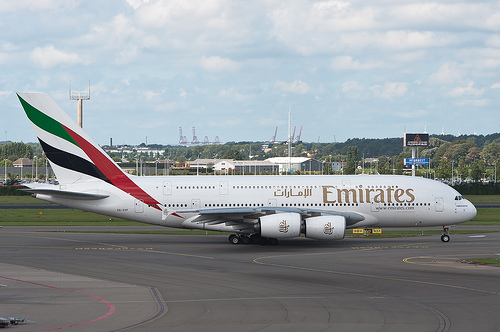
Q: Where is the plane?
A: On the runway.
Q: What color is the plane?
A: White.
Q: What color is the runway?
A: Gray.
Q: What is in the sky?
A: Clouds.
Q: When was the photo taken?
A: Daytime.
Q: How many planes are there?
A: One.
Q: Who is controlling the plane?
A: The pilot.